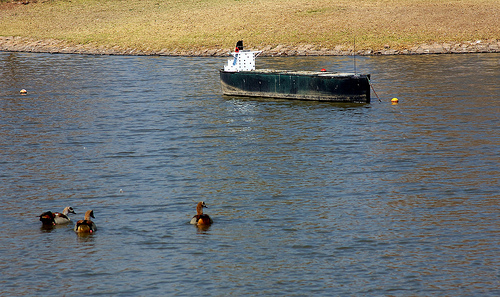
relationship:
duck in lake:
[188, 194, 218, 232] [8, 50, 495, 295]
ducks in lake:
[32, 199, 106, 242] [8, 50, 495, 295]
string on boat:
[366, 74, 391, 108] [213, 37, 373, 111]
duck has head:
[186, 194, 216, 235] [193, 197, 209, 211]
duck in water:
[186, 194, 216, 235] [148, 159, 275, 279]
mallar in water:
[72, 206, 101, 235] [22, 172, 149, 272]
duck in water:
[35, 203, 78, 226] [24, 175, 156, 273]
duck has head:
[186, 194, 216, 235] [193, 197, 209, 215]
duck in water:
[151, 185, 257, 247] [286, 171, 452, 272]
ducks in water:
[50, 161, 262, 278] [223, 148, 397, 245]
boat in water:
[194, 24, 424, 142] [273, 152, 435, 250]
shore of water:
[29, 24, 175, 105] [203, 131, 442, 234]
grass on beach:
[85, 3, 209, 56] [28, 6, 215, 92]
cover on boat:
[219, 30, 276, 95] [203, 24, 399, 135]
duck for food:
[37, 180, 98, 242] [83, 10, 259, 210]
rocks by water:
[366, 22, 483, 81] [270, 139, 464, 261]